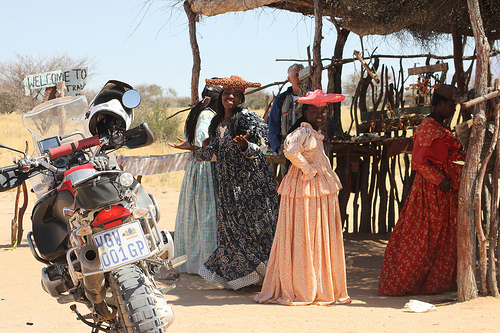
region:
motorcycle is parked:
[3, 78, 179, 332]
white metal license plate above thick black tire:
[93, 220, 146, 265]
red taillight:
[90, 203, 133, 230]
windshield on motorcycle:
[24, 93, 89, 145]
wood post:
[184, 2, 202, 102]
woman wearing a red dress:
[377, 83, 465, 295]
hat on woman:
[430, 83, 462, 101]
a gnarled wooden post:
[453, 0, 484, 298]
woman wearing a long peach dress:
[253, 90, 349, 302]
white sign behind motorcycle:
[24, 65, 88, 94]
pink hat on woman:
[296, 88, 346, 107]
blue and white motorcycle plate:
[89, 220, 158, 271]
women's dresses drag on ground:
[164, 245, 471, 302]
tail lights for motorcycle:
[69, 202, 153, 239]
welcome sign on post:
[23, 67, 95, 99]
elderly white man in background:
[269, 61, 317, 185]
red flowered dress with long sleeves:
[380, 112, 460, 295]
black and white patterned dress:
[192, 105, 277, 292]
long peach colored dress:
[257, 120, 352, 309]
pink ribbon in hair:
[200, 95, 215, 105]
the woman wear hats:
[211, 76, 342, 108]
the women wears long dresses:
[178, 80, 461, 298]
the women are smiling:
[225, 89, 324, 128]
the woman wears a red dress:
[378, 120, 476, 298]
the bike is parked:
[0, 84, 185, 331]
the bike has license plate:
[96, 226, 155, 266]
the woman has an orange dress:
[267, 126, 353, 305]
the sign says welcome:
[26, 70, 71, 92]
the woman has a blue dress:
[168, 108, 219, 275]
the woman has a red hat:
[297, 91, 340, 103]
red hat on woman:
[291, 88, 348, 108]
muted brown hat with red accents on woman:
[431, 75, 463, 101]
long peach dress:
[255, 119, 352, 311]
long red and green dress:
[373, 113, 468, 301]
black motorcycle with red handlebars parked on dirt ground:
[1, 75, 179, 330]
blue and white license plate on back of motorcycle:
[87, 213, 159, 275]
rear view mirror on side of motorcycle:
[105, 83, 147, 119]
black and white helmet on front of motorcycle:
[82, 76, 140, 143]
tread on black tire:
[111, 263, 173, 332]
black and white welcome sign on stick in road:
[19, 62, 96, 100]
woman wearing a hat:
[270, 83, 370, 320]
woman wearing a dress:
[257, 82, 358, 322]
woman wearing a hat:
[187, 75, 267, 278]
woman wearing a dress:
[181, 70, 257, 290]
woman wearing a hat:
[380, 76, 457, 291]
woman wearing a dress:
[367, 76, 462, 296]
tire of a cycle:
[101, 270, 166, 325]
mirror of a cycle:
[115, 86, 141, 108]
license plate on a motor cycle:
[90, 225, 160, 260]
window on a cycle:
[28, 88, 88, 139]